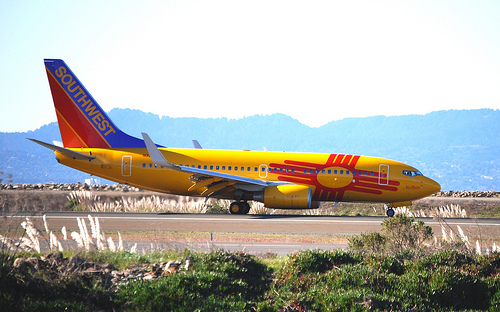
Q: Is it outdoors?
A: Yes, it is outdoors.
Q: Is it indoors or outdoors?
A: It is outdoors.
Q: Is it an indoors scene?
A: No, it is outdoors.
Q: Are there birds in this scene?
A: No, there are no birds.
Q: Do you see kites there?
A: No, there are no kites.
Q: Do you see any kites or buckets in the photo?
A: No, there are no kites or buckets.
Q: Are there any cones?
A: No, there are no cones.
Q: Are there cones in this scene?
A: No, there are no cones.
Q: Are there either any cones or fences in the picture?
A: No, there are no cones or fences.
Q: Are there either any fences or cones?
A: No, there are no cones or fences.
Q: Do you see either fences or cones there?
A: No, there are no cones or fences.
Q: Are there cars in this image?
A: No, there are no cars.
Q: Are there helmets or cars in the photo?
A: No, there are no cars or helmets.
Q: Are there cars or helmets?
A: No, there are no cars or helmets.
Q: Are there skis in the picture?
A: No, there are no skis.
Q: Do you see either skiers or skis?
A: No, there are no skis or skiers.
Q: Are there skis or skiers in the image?
A: No, there are no skis or skiers.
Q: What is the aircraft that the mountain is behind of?
A: The aircraft is an airplane.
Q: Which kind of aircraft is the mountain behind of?
A: The mountain is behind the plane.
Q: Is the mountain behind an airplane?
A: Yes, the mountain is behind an airplane.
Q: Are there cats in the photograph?
A: No, there are no cats.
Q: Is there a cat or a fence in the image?
A: No, there are no cats or fences.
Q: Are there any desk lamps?
A: No, there are no desk lamps.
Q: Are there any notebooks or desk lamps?
A: No, there are no desk lamps or notebooks.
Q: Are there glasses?
A: No, there are no glasses.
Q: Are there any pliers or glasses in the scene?
A: No, there are no glasses or pliers.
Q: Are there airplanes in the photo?
A: Yes, there is an airplane.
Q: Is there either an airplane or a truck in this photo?
A: Yes, there is an airplane.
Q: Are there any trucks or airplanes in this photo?
A: Yes, there is an airplane.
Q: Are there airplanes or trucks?
A: Yes, there is an airplane.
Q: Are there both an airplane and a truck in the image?
A: No, there is an airplane but no trucks.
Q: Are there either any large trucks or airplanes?
A: Yes, there is a large airplane.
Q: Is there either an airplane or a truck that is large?
A: Yes, the airplane is large.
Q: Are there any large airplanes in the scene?
A: Yes, there is a large airplane.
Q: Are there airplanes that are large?
A: Yes, there is an airplane that is large.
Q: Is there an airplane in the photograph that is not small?
A: Yes, there is a large airplane.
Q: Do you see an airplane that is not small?
A: Yes, there is a large airplane.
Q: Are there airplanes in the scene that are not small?
A: Yes, there is a large airplane.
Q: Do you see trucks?
A: No, there are no trucks.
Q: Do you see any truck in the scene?
A: No, there are no trucks.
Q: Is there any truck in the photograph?
A: No, there are no trucks.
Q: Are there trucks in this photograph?
A: No, there are no trucks.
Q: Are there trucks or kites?
A: No, there are no trucks or kites.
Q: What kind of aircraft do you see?
A: The aircraft is an airplane.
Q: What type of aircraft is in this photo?
A: The aircraft is an airplane.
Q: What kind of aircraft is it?
A: The aircraft is an airplane.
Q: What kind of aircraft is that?
A: This is an airplane.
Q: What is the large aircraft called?
A: The aircraft is an airplane.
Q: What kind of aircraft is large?
A: The aircraft is an airplane.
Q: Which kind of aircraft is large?
A: The aircraft is an airplane.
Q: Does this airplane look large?
A: Yes, the airplane is large.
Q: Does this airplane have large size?
A: Yes, the airplane is large.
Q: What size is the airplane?
A: The airplane is large.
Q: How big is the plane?
A: The plane is large.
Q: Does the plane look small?
A: No, the plane is large.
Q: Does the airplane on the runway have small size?
A: No, the plane is large.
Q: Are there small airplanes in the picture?
A: No, there is an airplane but it is large.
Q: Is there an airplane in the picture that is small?
A: No, there is an airplane but it is large.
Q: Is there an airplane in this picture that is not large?
A: No, there is an airplane but it is large.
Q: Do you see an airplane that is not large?
A: No, there is an airplane but it is large.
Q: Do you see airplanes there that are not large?
A: No, there is an airplane but it is large.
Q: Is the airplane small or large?
A: The airplane is large.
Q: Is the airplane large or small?
A: The airplane is large.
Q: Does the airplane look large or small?
A: The airplane is large.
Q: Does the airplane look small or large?
A: The airplane is large.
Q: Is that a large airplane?
A: Yes, that is a large airplane.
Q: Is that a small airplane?
A: No, that is a large airplane.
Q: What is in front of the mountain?
A: The airplane is in front of the mountain.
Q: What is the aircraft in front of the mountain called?
A: The aircraft is an airplane.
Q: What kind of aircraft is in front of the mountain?
A: The aircraft is an airplane.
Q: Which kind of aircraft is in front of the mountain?
A: The aircraft is an airplane.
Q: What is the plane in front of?
A: The plane is in front of the mountain.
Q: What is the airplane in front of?
A: The plane is in front of the mountain.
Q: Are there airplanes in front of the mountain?
A: Yes, there is an airplane in front of the mountain.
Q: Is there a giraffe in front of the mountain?
A: No, there is an airplane in front of the mountain.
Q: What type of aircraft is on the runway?
A: The aircraft is an airplane.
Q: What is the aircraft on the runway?
A: The aircraft is an airplane.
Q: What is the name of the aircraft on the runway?
A: The aircraft is an airplane.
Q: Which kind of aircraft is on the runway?
A: The aircraft is an airplane.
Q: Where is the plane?
A: The plane is on the runway.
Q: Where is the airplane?
A: The plane is on the runway.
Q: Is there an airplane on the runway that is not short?
A: Yes, there is an airplane on the runway.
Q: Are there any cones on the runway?
A: No, there is an airplane on the runway.